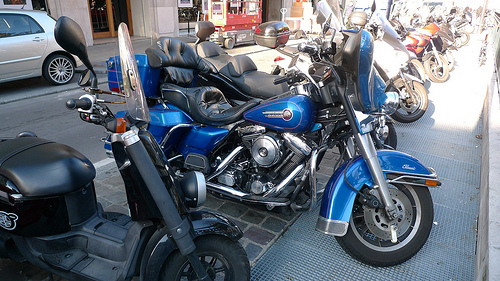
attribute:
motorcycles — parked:
[1, 1, 494, 280]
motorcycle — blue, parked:
[109, 28, 442, 269]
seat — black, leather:
[156, 34, 255, 128]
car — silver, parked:
[3, 8, 88, 88]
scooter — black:
[3, 19, 250, 280]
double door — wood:
[87, 2, 141, 43]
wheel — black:
[315, 152, 444, 264]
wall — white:
[470, 16, 500, 276]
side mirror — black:
[54, 18, 95, 90]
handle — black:
[62, 94, 91, 111]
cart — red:
[197, 2, 264, 33]